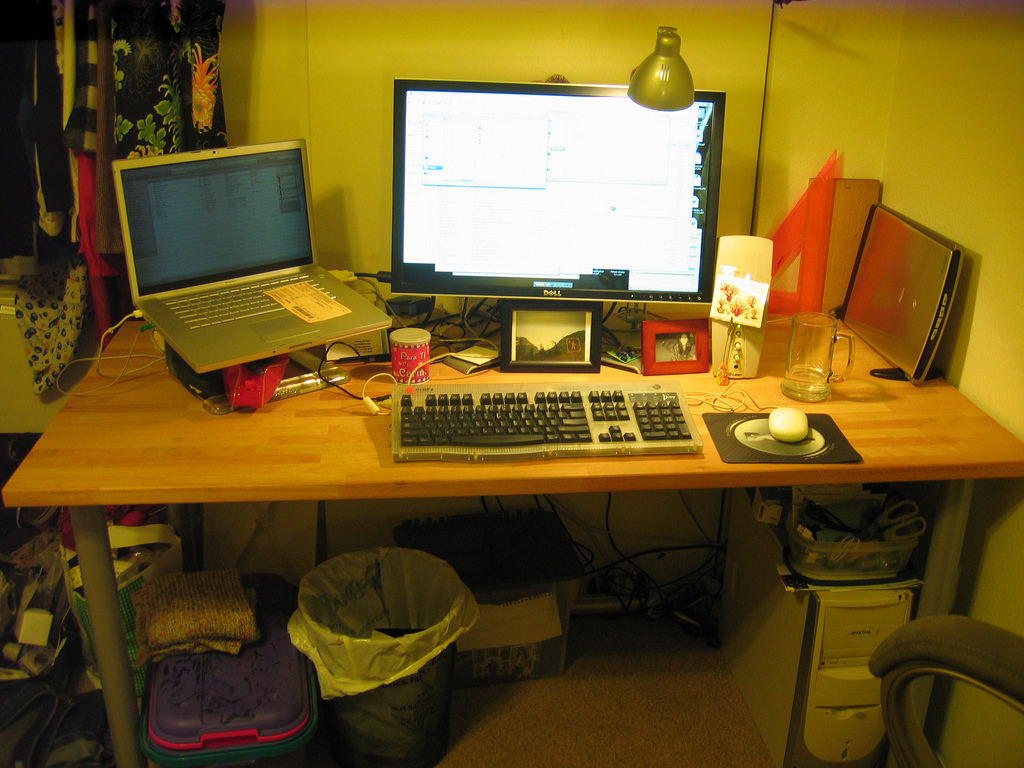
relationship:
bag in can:
[272, 530, 489, 699] [305, 543, 486, 763]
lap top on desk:
[112, 123, 391, 371] [0, 312, 1022, 496]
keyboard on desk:
[385, 369, 703, 455] [0, 287, 1022, 485]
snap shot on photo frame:
[653, 313, 707, 370] [633, 318, 716, 371]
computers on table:
[9, 5, 999, 372] [0, 270, 1022, 502]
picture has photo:
[638, 311, 714, 370] [650, 326, 690, 359]